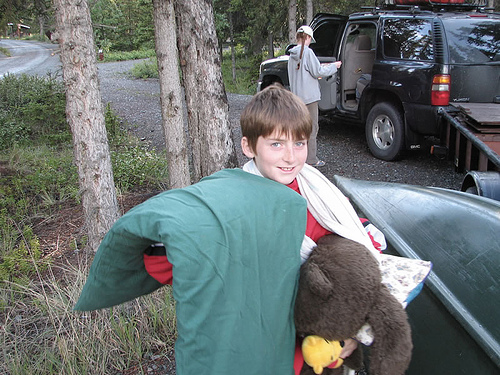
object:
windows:
[439, 17, 499, 66]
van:
[255, 2, 500, 164]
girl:
[287, 24, 343, 167]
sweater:
[285, 43, 337, 106]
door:
[308, 11, 348, 113]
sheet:
[242, 159, 381, 268]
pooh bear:
[297, 334, 346, 375]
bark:
[152, 0, 193, 189]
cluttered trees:
[51, 0, 121, 254]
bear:
[290, 233, 414, 375]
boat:
[331, 173, 500, 375]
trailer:
[437, 101, 500, 202]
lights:
[431, 73, 452, 84]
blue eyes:
[270, 142, 283, 148]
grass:
[0, 68, 178, 375]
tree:
[150, 0, 191, 189]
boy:
[140, 83, 389, 375]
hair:
[240, 85, 313, 156]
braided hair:
[294, 32, 307, 71]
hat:
[296, 25, 317, 44]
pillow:
[70, 167, 310, 375]